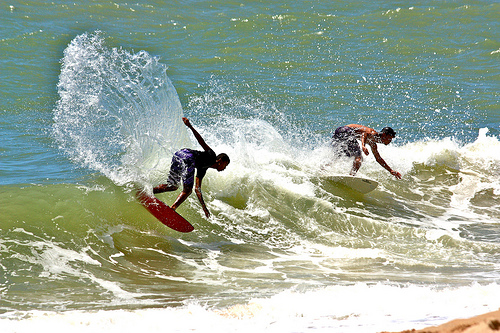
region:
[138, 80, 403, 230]
two surfers riding the same ave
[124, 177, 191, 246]
surfboard with red bottom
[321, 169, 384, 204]
surfboard with white bottom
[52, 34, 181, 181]
splash created by surfer on red board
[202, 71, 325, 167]
splash created by surfer on white board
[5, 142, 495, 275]
wave the surfers are riding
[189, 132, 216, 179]
black shirt surfer is wearing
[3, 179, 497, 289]
swell of the wave surfers are riding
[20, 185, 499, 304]
white foam in the water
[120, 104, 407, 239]
two surfers in the water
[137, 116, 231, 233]
A person on a surfboard.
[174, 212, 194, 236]
Part of a red surfboard.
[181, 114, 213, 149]
The man's arm.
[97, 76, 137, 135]
Part of a wave.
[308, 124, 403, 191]
A man on a surfboard.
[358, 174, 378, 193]
Part of a white surfboard.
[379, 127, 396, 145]
The head of the man.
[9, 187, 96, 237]
Part of a wave.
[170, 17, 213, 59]
Part of the calm water.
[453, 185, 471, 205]
White foamy water.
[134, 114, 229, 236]
surfer with blue pants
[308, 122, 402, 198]
surfer with no shirt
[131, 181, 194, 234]
red surfboard in use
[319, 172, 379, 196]
white surfboard in use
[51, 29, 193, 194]
plume of water behind surfer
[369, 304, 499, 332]
sand near to water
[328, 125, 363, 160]
dark swimming trunks being worn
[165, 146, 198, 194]
blue pants or swimming trunks being worn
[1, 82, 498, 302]
wave of water with surfers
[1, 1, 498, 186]
body of water behind surfers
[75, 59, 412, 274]
two boys trying to surf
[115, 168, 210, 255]
a red surfboard in water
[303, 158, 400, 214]
a white surfboard in water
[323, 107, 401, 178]
a boy with only shorts on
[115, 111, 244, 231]
on boy with shorts and a shirt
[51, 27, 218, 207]
a wall of water sprayed in air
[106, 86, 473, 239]
two boys riding the wave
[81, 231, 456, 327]
white foamy water from waves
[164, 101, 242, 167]
one arm way out in back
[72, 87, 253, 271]
a surfer on a red board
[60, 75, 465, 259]
two surfers riding waves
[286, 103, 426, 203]
a surfer riding a wave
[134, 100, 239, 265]
a surfer riding a wave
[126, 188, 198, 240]
a red surfboard on a wave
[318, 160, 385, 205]
a white surfboard on a wave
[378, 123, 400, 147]
the head of a surfer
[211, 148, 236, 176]
the head of a surfer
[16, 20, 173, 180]
the splash of a surfboard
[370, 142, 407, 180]
the arm of a surfer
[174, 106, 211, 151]
the arm of a surfer